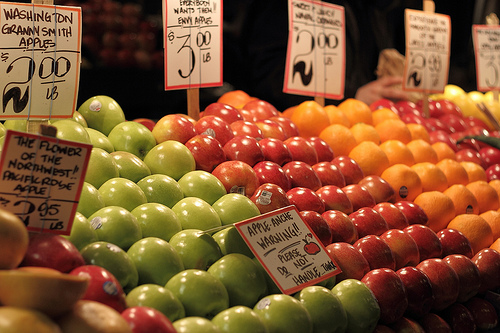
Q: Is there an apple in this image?
A: Yes, there are apples.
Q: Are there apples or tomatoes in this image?
A: Yes, there are apples.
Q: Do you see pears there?
A: No, there are no pears.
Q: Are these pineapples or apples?
A: These are apples.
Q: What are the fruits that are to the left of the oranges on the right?
A: The fruits are apples.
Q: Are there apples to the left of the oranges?
A: Yes, there are apples to the left of the oranges.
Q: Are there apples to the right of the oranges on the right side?
A: No, the apples are to the left of the oranges.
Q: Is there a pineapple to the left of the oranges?
A: No, there are apples to the left of the oranges.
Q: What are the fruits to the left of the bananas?
A: The fruits are apples.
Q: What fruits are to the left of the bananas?
A: The fruits are apples.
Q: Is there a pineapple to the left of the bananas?
A: No, there are apples to the left of the bananas.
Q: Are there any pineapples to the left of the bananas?
A: No, there are apples to the left of the bananas.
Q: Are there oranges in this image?
A: Yes, there are oranges.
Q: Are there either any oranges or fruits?
A: Yes, there are oranges.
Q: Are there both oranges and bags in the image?
A: No, there are oranges but no bags.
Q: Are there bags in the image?
A: No, there are no bags.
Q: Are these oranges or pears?
A: These are oranges.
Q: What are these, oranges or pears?
A: These are oranges.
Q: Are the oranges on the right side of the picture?
A: Yes, the oranges are on the right of the image.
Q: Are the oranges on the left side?
A: No, the oranges are on the right of the image.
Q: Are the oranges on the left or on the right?
A: The oranges are on the right of the image.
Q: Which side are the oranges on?
A: The oranges are on the right of the image.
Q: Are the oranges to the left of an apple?
A: No, the oranges are to the right of an apple.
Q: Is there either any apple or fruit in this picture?
A: Yes, there is an apple.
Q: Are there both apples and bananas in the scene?
A: Yes, there are both an apple and bananas.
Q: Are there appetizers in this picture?
A: No, there are no appetizers.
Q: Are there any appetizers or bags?
A: No, there are no appetizers or bags.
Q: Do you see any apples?
A: Yes, there are apples.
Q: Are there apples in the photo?
A: Yes, there are apples.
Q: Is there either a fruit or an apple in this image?
A: Yes, there are apples.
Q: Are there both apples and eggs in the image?
A: No, there are apples but no eggs.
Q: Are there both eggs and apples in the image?
A: No, there are apples but no eggs.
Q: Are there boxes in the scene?
A: No, there are no boxes.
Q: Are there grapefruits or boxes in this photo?
A: No, there are no boxes or grapefruits.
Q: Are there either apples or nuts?
A: Yes, there are apples.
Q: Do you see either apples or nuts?
A: Yes, there are apples.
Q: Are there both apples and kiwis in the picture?
A: No, there are apples but no kiwis.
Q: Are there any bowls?
A: No, there are no bowls.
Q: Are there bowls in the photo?
A: No, there are no bowls.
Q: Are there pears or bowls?
A: No, there are no bowls or pears.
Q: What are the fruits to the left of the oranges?
A: The fruits are apples.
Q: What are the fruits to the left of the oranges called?
A: The fruits are apples.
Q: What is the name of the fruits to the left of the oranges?
A: The fruits are apples.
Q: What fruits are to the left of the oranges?
A: The fruits are apples.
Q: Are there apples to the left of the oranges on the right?
A: Yes, there are apples to the left of the oranges.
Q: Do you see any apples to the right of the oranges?
A: No, the apples are to the left of the oranges.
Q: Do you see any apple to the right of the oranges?
A: No, the apples are to the left of the oranges.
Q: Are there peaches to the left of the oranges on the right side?
A: No, there are apples to the left of the oranges.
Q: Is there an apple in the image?
A: Yes, there are apples.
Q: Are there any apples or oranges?
A: Yes, there are apples.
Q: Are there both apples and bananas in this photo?
A: Yes, there are both apples and a banana.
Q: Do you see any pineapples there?
A: No, there are no pineapples.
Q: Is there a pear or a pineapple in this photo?
A: No, there are no pineapples or pears.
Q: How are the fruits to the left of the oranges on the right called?
A: The fruits are apples.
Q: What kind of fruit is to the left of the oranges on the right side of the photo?
A: The fruits are apples.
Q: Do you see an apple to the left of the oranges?
A: Yes, there are apples to the left of the oranges.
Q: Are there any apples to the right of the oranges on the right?
A: No, the apples are to the left of the oranges.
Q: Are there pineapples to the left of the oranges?
A: No, there are apples to the left of the oranges.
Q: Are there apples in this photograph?
A: Yes, there is an apple.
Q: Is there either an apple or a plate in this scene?
A: Yes, there is an apple.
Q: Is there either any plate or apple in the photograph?
A: Yes, there is an apple.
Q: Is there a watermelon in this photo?
A: No, there are no watermelons.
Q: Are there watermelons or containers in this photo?
A: No, there are no watermelons or containers.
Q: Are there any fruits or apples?
A: Yes, there is an apple.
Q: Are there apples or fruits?
A: Yes, there is an apple.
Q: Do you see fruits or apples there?
A: Yes, there is an apple.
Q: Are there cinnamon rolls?
A: No, there are no cinnamon rolls.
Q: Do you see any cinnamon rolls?
A: No, there are no cinnamon rolls.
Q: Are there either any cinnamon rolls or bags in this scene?
A: No, there are no cinnamon rolls or bags.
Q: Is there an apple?
A: Yes, there is an apple.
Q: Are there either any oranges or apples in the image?
A: Yes, there is an apple.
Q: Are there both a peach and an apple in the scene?
A: No, there is an apple but no peaches.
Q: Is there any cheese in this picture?
A: No, there is no cheese.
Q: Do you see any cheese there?
A: No, there is no cheese.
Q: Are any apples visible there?
A: Yes, there are apples.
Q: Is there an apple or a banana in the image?
A: Yes, there are apples.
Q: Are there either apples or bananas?
A: Yes, there are apples.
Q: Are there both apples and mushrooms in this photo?
A: No, there are apples but no mushrooms.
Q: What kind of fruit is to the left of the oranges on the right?
A: The fruits are apples.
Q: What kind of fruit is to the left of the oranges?
A: The fruits are apples.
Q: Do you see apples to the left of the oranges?
A: Yes, there are apples to the left of the oranges.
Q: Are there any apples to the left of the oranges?
A: Yes, there are apples to the left of the oranges.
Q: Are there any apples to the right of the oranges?
A: No, the apples are to the left of the oranges.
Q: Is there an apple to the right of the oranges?
A: No, the apples are to the left of the oranges.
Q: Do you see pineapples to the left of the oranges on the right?
A: No, there are apples to the left of the oranges.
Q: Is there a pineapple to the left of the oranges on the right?
A: No, there are apples to the left of the oranges.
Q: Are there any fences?
A: No, there are no fences.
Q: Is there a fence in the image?
A: No, there are no fences.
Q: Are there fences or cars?
A: No, there are no fences or cars.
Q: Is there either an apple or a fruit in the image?
A: Yes, there is an apple.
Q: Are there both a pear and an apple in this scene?
A: No, there is an apple but no pears.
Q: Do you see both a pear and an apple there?
A: No, there is an apple but no pears.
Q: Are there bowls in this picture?
A: No, there are no bowls.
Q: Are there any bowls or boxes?
A: No, there are no bowls or boxes.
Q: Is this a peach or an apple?
A: This is an apple.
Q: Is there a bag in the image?
A: No, there are no bags.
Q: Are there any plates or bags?
A: No, there are no bags or plates.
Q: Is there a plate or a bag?
A: No, there are no bags or plates.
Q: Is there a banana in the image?
A: Yes, there are bananas.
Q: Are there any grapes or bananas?
A: Yes, there are bananas.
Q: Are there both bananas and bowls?
A: No, there are bananas but no bowls.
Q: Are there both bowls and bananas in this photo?
A: No, there are bananas but no bowls.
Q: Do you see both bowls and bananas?
A: No, there are bananas but no bowls.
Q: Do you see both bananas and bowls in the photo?
A: No, there are bananas but no bowls.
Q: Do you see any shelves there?
A: No, there are no shelves.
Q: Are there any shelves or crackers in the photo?
A: No, there are no shelves or crackers.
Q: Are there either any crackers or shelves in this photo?
A: No, there are no shelves or crackers.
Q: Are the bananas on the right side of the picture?
A: Yes, the bananas are on the right of the image.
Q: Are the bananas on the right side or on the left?
A: The bananas are on the right of the image.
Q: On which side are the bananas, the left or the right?
A: The bananas are on the right of the image.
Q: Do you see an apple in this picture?
A: Yes, there is an apple.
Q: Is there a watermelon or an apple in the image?
A: Yes, there is an apple.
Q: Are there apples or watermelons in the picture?
A: Yes, there is an apple.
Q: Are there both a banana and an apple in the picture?
A: Yes, there are both an apple and a banana.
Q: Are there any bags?
A: No, there are no bags.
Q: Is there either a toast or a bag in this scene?
A: No, there are no bags or toasts.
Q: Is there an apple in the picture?
A: Yes, there are apples.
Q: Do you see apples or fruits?
A: Yes, there are apples.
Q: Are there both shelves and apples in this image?
A: No, there are apples but no shelves.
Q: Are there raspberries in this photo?
A: No, there are no raspberries.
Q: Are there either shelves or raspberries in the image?
A: No, there are no raspberries or shelves.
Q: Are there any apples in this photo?
A: Yes, there are apples.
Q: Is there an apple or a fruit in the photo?
A: Yes, there are apples.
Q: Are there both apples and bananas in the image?
A: Yes, there are both apples and bananas.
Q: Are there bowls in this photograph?
A: No, there are no bowls.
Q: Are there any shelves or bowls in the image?
A: No, there are no bowls or shelves.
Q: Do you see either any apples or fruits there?
A: Yes, there are apples.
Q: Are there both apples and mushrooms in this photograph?
A: No, there are apples but no mushrooms.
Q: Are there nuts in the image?
A: No, there are no nuts.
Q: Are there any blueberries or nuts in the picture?
A: No, there are no nuts or blueberries.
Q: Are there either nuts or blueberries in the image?
A: No, there are no nuts or blueberries.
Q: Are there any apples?
A: Yes, there is an apple.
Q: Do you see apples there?
A: Yes, there is an apple.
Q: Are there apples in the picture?
A: Yes, there is an apple.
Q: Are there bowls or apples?
A: Yes, there is an apple.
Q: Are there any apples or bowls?
A: Yes, there is an apple.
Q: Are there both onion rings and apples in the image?
A: No, there is an apple but no onion rings.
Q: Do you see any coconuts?
A: No, there are no coconuts.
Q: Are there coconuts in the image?
A: No, there are no coconuts.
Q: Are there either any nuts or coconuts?
A: No, there are no coconuts or nuts.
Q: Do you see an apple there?
A: Yes, there is an apple.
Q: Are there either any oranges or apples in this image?
A: Yes, there is an apple.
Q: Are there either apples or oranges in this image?
A: Yes, there is an apple.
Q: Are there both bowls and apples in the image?
A: No, there is an apple but no bowls.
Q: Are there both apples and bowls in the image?
A: No, there is an apple but no bowls.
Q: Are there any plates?
A: No, there are no plates.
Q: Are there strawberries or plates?
A: No, there are no plates or strawberries.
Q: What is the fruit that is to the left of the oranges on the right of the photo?
A: The fruit is an apple.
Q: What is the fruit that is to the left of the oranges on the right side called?
A: The fruit is an apple.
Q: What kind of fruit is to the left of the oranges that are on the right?
A: The fruit is an apple.